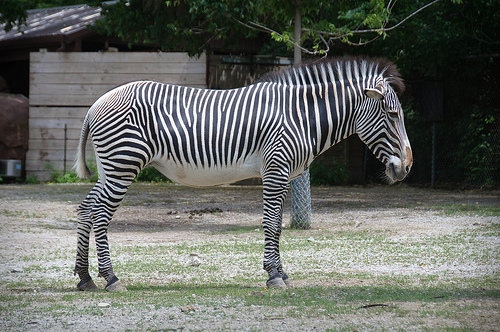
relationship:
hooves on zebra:
[265, 274, 289, 292] [72, 54, 414, 295]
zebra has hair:
[72, 54, 414, 295] [259, 52, 444, 94]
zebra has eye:
[72, 54, 414, 295] [385, 105, 399, 122]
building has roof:
[2, 4, 364, 183] [0, 2, 120, 47]